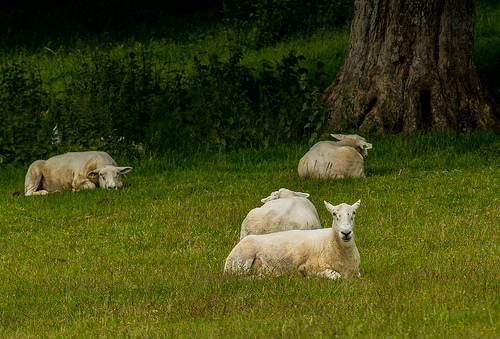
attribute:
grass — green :
[1, 0, 499, 337]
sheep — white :
[240, 98, 413, 337]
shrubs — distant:
[0, 7, 499, 156]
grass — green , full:
[1, 128, 497, 336]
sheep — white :
[207, 173, 400, 309]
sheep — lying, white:
[293, 131, 373, 181]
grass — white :
[420, 172, 496, 328]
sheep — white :
[244, 189, 315, 229]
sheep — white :
[27, 150, 133, 207]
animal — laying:
[220, 200, 362, 285]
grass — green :
[109, 259, 172, 303]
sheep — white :
[216, 197, 371, 281]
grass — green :
[387, 189, 497, 306]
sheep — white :
[222, 195, 362, 287]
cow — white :
[225, 182, 447, 322]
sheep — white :
[298, 132, 374, 179]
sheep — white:
[25, 88, 392, 323]